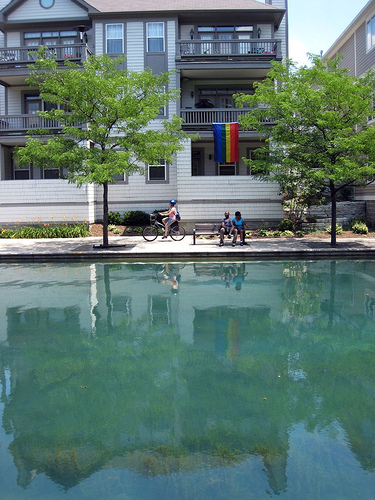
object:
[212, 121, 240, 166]
flag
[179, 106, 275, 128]
deck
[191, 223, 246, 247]
bench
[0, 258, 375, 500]
water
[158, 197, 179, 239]
person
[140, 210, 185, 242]
bicycle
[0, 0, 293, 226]
building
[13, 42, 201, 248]
tree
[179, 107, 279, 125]
wooden railing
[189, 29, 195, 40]
light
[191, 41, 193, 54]
pole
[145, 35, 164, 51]
window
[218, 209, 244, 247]
two people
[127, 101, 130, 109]
leaves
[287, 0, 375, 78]
sky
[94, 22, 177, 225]
wall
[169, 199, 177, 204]
helmet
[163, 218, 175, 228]
shorts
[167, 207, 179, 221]
pink shirt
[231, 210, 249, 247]
person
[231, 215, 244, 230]
blue shirt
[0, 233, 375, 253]
sidewalk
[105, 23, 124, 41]
window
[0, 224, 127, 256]
shadow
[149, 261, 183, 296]
reflections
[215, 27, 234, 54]
door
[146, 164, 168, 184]
window